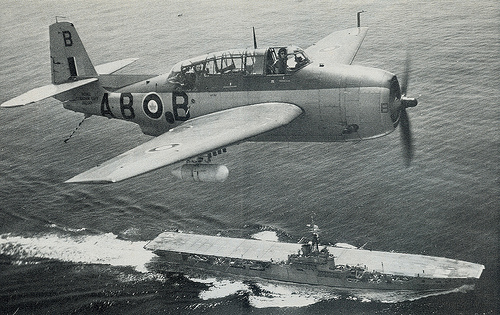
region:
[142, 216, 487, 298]
an aircraft carrier on the water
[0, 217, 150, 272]
wake behind an aircraft carrier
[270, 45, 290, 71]
the pilot in an airplane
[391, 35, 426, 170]
a spinning propeller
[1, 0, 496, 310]
dark ocean water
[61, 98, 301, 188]
the wing of an airplane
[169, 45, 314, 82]
the cockpit of an airplane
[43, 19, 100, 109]
the tail of an airplane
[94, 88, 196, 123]
black letters on the side of a plane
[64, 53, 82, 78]
a black stripe on an airplane tail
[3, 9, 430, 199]
old fashioned plane in air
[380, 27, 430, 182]
propeller turning on airplane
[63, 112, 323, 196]
wing of airplane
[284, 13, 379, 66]
wing of airplane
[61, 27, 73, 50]
letter b on tail of airplane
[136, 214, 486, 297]
airplane carrier in water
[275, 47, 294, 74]
pilot in airplane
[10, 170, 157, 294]
waves in water behind carrier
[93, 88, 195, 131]
A B O B on airplane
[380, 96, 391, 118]
small b on airplane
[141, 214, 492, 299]
military style aircraft carrier in the water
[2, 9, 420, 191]
military style airplane flying over water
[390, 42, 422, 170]
moving airplane propeller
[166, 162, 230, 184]
bomb attached to aircraft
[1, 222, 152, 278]
wake created by large ship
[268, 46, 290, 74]
pilot flying military aircraft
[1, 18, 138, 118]
tailfin of military plane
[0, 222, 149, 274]
water disturbance created by aircraft carrier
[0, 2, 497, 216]
open ocean undisturbed by vessels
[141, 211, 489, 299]
military vessel on open water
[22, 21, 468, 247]
an airplane in the air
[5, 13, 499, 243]
a plane in the air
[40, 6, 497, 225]
a small plane in the air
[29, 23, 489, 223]
a small airplane in the air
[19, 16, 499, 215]
a plane flying above the water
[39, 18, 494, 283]
an airplane flying above the water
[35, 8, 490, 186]
a plane flying in the air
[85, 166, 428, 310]
a boat in the water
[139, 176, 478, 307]
a large boat in the water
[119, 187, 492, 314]
a large boat moving in the water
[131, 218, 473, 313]
the ship on the water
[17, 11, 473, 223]
the plane is flying